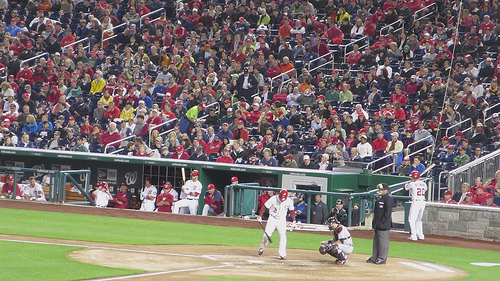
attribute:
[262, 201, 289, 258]
clothes — white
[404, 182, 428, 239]
clothes — white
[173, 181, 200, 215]
clothes — white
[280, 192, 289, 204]
helmet — red, shiny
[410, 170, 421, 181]
helmet — red, shiny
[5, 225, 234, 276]
grass — green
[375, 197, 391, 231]
jacket — black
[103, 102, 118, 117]
spectator — sitting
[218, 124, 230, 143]
spectator — sitting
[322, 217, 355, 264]
man — squatting, crouched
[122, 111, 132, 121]
shirt — yellow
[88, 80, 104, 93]
shirt — yellow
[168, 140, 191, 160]
person — sitting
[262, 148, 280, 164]
person — sitting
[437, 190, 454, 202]
person — sitting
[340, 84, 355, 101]
person — sitting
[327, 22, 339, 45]
person — sitting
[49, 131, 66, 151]
person — sitting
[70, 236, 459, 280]
circle — brown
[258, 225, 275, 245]
bat — black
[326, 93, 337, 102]
shirt — green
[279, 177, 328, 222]
door — large, white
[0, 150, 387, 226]
dugout — green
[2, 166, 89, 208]
fence — chain link, green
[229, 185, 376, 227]
fence — chain link, green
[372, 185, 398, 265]
umpire — waiting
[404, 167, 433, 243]
player — waiting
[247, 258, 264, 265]
home plate — white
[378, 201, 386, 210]
writing — white